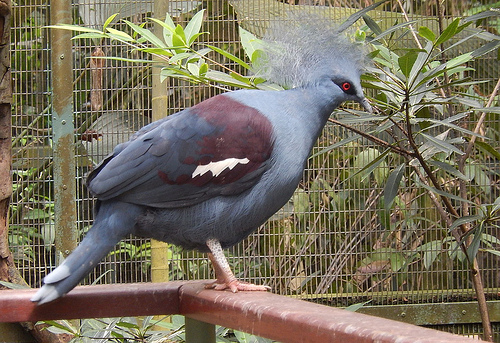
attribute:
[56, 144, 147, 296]
tail — long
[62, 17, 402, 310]
feather — fluffy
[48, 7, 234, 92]
leaves — green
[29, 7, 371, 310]
feathers — white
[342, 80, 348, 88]
eye — red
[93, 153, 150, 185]
feather — grey, white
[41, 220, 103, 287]
feather — grey, white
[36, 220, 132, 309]
feather — grey, white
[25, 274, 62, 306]
feather — grey, white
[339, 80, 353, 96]
eye — red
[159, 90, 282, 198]
feathers — dark red